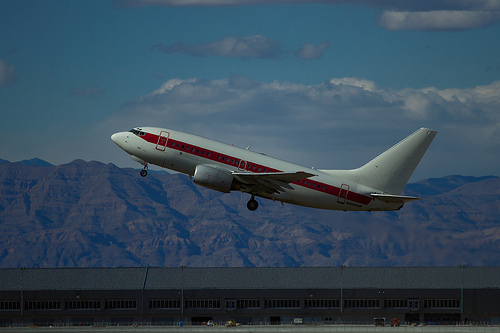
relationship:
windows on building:
[261, 294, 302, 314] [34, 274, 476, 324]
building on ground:
[0, 262, 500, 326] [0, 323, 498, 330]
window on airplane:
[170, 140, 175, 145] [109, 126, 440, 213]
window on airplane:
[174, 141, 181, 148] [109, 126, 440, 213]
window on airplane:
[180, 143, 185, 149] [109, 126, 440, 213]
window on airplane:
[189, 147, 196, 153] [109, 126, 440, 213]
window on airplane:
[215, 153, 221, 160] [109, 126, 440, 213]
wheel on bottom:
[245, 200, 264, 210] [254, 189, 292, 201]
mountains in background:
[0, 148, 500, 267] [12, 77, 485, 254]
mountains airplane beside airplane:
[7, 211, 499, 286] [112, 113, 421, 223]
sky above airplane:
[1, 0, 498, 182] [111, 125, 436, 210]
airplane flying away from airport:
[109, 126, 440, 213] [12, 261, 494, 321]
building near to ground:
[0, 269, 489, 331] [0, 323, 497, 333]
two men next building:
[19, 151, 124, 261] [0, 269, 489, 331]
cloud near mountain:
[35, 76, 497, 189] [5, 149, 498, 266]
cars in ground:
[195, 316, 251, 325] [173, 325, 454, 331]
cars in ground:
[199, 315, 220, 327] [173, 325, 454, 331]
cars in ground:
[224, 320, 241, 327] [173, 325, 454, 331]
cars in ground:
[382, 316, 410, 331] [173, 325, 454, 331]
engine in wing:
[194, 163, 231, 195] [230, 170, 318, 183]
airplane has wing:
[109, 126, 440, 213] [230, 170, 318, 183]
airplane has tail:
[98, 111, 446, 222] [348, 121, 442, 193]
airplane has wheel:
[109, 126, 440, 213] [248, 200, 259, 210]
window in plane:
[171, 142, 175, 146] [109, 0, 437, 110]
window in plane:
[181, 145, 185, 149] [109, 0, 437, 110]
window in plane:
[192, 143, 203, 157] [109, 0, 437, 110]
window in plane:
[202, 147, 212, 157] [109, 0, 437, 110]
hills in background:
[3, 159, 496, 264] [3, 94, 497, 288]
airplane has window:
[109, 126, 440, 213] [167, 136, 176, 146]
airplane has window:
[109, 126, 440, 213] [181, 141, 190, 153]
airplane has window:
[109, 126, 440, 213] [194, 146, 204, 156]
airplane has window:
[109, 126, 440, 213] [211, 153, 220, 160]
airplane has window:
[109, 126, 440, 213] [224, 158, 239, 164]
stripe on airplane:
[139, 130, 373, 205] [109, 126, 440, 213]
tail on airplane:
[357, 126, 439, 195] [109, 126, 440, 213]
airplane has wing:
[109, 126, 440, 213] [231, 170, 320, 190]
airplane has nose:
[109, 126, 440, 213] [107, 127, 134, 154]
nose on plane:
[103, 122, 143, 159] [109, 106, 444, 226]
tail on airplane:
[365, 111, 437, 218] [111, 125, 436, 210]